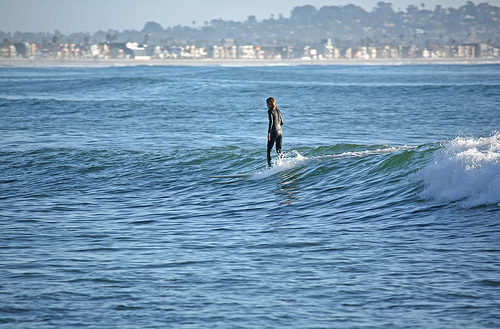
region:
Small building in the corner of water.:
[115, 35, 145, 65]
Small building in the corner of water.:
[380, 37, 450, 70]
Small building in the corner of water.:
[261, 21, 267, 56]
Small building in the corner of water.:
[10, 25, 22, 59]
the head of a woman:
[251, 88, 293, 123]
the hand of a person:
[251, 117, 293, 143]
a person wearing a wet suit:
[260, 52, 318, 158]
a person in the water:
[219, 65, 370, 197]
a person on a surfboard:
[245, 92, 321, 176]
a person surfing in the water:
[217, 62, 349, 212]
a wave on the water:
[215, 84, 478, 249]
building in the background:
[108, 25, 411, 82]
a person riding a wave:
[216, 51, 358, 196]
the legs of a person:
[258, 118, 305, 165]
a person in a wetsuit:
[265, 91, 285, 166]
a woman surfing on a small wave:
[265, 90, 290, 171]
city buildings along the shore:
[3, 36, 498, 56]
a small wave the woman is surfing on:
[191, 130, 498, 220]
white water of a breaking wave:
[430, 130, 498, 202]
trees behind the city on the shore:
[2, 5, 497, 41]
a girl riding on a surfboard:
[265, 92, 285, 164]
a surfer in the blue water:
[265, 92, 286, 167]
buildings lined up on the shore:
[1, 39, 498, 61]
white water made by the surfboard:
[258, 147, 304, 178]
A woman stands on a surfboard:
[261, 93, 299, 176]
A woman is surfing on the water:
[234, 80, 331, 194]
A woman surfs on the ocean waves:
[213, 80, 354, 199]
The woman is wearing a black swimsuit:
[255, 88, 292, 174]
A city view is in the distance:
[0, 31, 491, 59]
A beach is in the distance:
[7, 54, 497, 65]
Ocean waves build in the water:
[338, 133, 498, 213]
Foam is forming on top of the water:
[409, 124, 498, 230]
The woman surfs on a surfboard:
[239, 88, 302, 184]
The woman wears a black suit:
[235, 83, 296, 180]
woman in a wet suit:
[256, 90, 301, 170]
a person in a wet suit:
[254, 94, 291, 175]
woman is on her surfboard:
[256, 94, 297, 165]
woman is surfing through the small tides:
[250, 92, 310, 184]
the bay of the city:
[3, 13, 499, 73]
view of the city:
[0, 21, 497, 72]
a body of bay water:
[95, 218, 392, 318]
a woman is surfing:
[246, 81, 316, 183]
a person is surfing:
[241, 86, 315, 190]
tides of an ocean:
[401, 120, 498, 202]